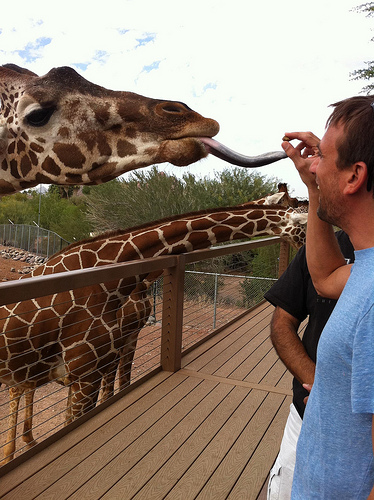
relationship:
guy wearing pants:
[266, 229, 355, 499] [254, 403, 309, 497]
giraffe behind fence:
[1, 182, 308, 467] [1, 236, 290, 474]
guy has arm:
[261, 229, 356, 498] [268, 303, 315, 392]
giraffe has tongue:
[41, 48, 181, 229] [192, 126, 319, 183]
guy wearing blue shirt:
[278, 95, 374, 499] [289, 248, 373, 498]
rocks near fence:
[6, 246, 44, 276] [1, 215, 62, 255]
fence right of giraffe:
[0, 236, 290, 474] [0, 63, 287, 198]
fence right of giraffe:
[0, 236, 290, 474] [1, 182, 308, 467]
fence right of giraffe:
[0, 236, 290, 474] [2, 205, 309, 424]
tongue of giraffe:
[183, 121, 298, 178] [0, 46, 294, 204]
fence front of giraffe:
[1, 236, 290, 474] [0, 63, 287, 198]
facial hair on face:
[313, 177, 353, 233] [308, 109, 360, 227]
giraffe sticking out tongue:
[0, 63, 287, 198] [196, 135, 286, 172]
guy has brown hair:
[278, 95, 374, 499] [324, 94, 372, 193]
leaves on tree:
[131, 172, 150, 183] [117, 149, 300, 266]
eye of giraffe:
[21, 105, 55, 128] [0, 63, 219, 198]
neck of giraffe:
[131, 203, 271, 268] [2, 183, 340, 467]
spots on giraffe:
[49, 138, 110, 172] [2, 58, 246, 187]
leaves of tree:
[348, 3, 373, 95] [1, 165, 305, 273]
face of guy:
[306, 116, 347, 228] [278, 95, 374, 499]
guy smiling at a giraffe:
[278, 82, 362, 230] [5, 51, 289, 220]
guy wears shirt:
[266, 229, 355, 499] [244, 217, 367, 420]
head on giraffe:
[1, 62, 219, 197] [0, 63, 287, 198]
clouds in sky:
[5, 9, 347, 168] [106, 20, 251, 92]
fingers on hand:
[277, 128, 321, 164] [278, 130, 330, 191]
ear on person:
[344, 160, 372, 200] [279, 94, 373, 450]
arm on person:
[252, 241, 323, 389] [249, 208, 368, 499]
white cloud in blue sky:
[278, 58, 314, 91] [19, 49, 30, 60]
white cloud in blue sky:
[0, 0, 373, 198] [19, 49, 30, 60]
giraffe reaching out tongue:
[0, 63, 287, 198] [187, 128, 286, 169]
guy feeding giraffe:
[278, 95, 374, 499] [3, 56, 320, 192]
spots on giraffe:
[153, 209, 283, 251] [1, 56, 247, 207]